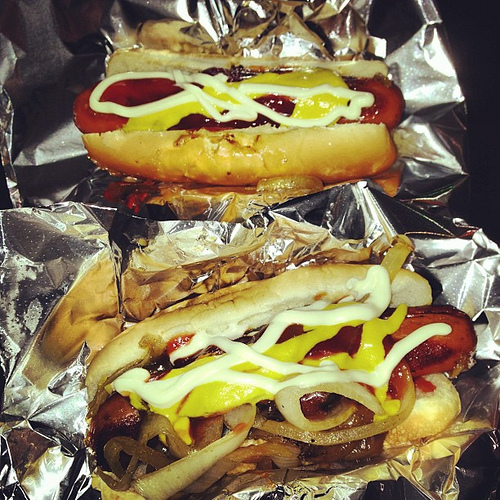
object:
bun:
[72, 47, 407, 194]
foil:
[0, 0, 500, 500]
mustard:
[118, 69, 407, 450]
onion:
[96, 375, 416, 493]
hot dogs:
[71, 73, 477, 474]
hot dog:
[73, 75, 404, 134]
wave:
[0, 199, 79, 310]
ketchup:
[89, 68, 407, 450]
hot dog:
[85, 303, 477, 471]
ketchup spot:
[140, 331, 197, 383]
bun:
[84, 264, 477, 500]